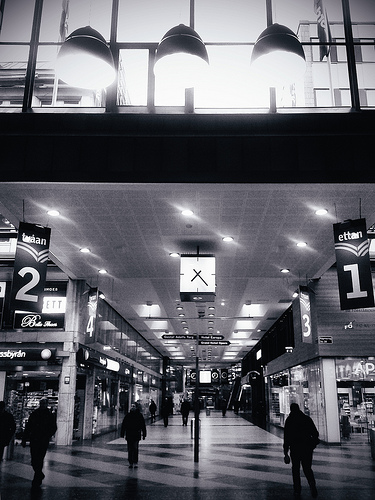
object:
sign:
[160, 334, 194, 342]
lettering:
[200, 334, 223, 339]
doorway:
[71, 374, 88, 445]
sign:
[199, 333, 223, 338]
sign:
[198, 341, 231, 345]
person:
[119, 401, 149, 474]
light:
[176, 320, 188, 331]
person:
[281, 403, 321, 500]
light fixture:
[249, 23, 307, 91]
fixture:
[53, 23, 118, 96]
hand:
[192, 269, 208, 286]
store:
[263, 343, 373, 444]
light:
[216, 328, 219, 333]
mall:
[0, 0, 374, 499]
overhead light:
[174, 302, 182, 314]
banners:
[4, 221, 50, 319]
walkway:
[0, 414, 374, 500]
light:
[298, 240, 306, 247]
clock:
[178, 255, 215, 295]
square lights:
[238, 301, 266, 318]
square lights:
[234, 317, 263, 331]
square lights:
[227, 328, 255, 341]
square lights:
[135, 301, 160, 319]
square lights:
[141, 318, 169, 332]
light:
[150, 0, 212, 92]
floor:
[0, 407, 374, 499]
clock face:
[179, 257, 215, 295]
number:
[302, 311, 312, 338]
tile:
[105, 424, 286, 445]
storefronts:
[0, 327, 95, 449]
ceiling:
[0, 182, 374, 372]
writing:
[163, 334, 198, 340]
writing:
[194, 333, 228, 342]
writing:
[193, 337, 229, 346]